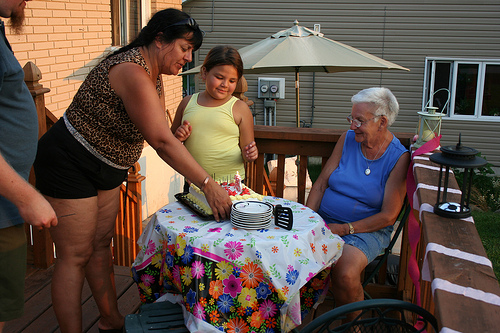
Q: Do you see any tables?
A: Yes, there is a table.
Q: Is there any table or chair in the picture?
A: Yes, there is a table.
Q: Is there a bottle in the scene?
A: No, there are no bottles.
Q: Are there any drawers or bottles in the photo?
A: No, there are no bottles or drawers.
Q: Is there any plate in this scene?
A: Yes, there is a plate.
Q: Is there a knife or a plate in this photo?
A: Yes, there is a plate.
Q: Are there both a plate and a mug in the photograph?
A: No, there is a plate but no mugs.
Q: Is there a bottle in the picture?
A: No, there are no bottles.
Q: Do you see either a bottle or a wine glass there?
A: No, there are no bottles or wine glasses.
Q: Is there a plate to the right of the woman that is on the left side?
A: Yes, there is a plate to the right of the woman.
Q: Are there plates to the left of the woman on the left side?
A: No, the plate is to the right of the woman.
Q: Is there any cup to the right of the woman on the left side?
A: No, there is a plate to the right of the woman.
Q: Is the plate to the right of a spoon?
A: No, the plate is to the right of the woman.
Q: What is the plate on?
A: The plate is on the table.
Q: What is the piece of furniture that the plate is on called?
A: The piece of furniture is a table.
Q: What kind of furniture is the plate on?
A: The plate is on the table.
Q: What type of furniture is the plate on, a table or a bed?
A: The plate is on a table.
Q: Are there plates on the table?
A: Yes, there is a plate on the table.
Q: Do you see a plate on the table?
A: Yes, there is a plate on the table.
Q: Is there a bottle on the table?
A: No, there is a plate on the table.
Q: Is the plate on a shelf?
A: No, the plate is on the table.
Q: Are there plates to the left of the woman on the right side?
A: Yes, there is a plate to the left of the woman.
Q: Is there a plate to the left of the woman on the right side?
A: Yes, there is a plate to the left of the woman.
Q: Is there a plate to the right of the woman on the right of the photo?
A: No, the plate is to the left of the woman.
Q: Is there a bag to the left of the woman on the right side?
A: No, there is a plate to the left of the woman.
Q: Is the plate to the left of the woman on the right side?
A: Yes, the plate is to the left of the woman.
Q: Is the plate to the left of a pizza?
A: No, the plate is to the left of the woman.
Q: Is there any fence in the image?
A: No, there are no fences.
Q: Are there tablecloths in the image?
A: Yes, there is a tablecloth.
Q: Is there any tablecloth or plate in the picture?
A: Yes, there is a tablecloth.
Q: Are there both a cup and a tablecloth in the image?
A: No, there is a tablecloth but no cups.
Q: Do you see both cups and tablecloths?
A: No, there is a tablecloth but no cups.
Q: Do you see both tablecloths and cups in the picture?
A: No, there is a tablecloth but no cups.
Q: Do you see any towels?
A: No, there are no towels.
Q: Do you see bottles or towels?
A: No, there are no towels or bottles.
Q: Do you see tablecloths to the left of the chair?
A: Yes, there is a tablecloth to the left of the chair.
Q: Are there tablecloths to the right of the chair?
A: No, the tablecloth is to the left of the chair.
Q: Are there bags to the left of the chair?
A: No, there is a tablecloth to the left of the chair.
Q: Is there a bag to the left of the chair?
A: No, there is a tablecloth to the left of the chair.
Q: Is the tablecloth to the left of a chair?
A: Yes, the tablecloth is to the left of a chair.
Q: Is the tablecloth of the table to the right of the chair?
A: No, the tablecloth is to the left of the chair.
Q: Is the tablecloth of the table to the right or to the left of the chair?
A: The tablecloth is to the left of the chair.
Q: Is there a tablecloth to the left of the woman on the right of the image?
A: Yes, there is a tablecloth to the left of the woman.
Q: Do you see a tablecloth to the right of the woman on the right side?
A: No, the tablecloth is to the left of the woman.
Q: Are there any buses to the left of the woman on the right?
A: No, there is a tablecloth to the left of the woman.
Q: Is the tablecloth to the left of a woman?
A: Yes, the tablecloth is to the left of a woman.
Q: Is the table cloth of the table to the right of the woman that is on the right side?
A: No, the tablecloth is to the left of the woman.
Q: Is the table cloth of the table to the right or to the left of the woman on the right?
A: The tablecloth is to the left of the woman.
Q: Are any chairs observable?
A: Yes, there is a chair.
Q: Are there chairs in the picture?
A: Yes, there is a chair.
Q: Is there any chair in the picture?
A: Yes, there is a chair.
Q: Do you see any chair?
A: Yes, there is a chair.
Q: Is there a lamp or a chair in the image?
A: Yes, there is a chair.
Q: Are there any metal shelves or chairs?
A: Yes, there is a metal chair.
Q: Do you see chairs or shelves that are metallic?
A: Yes, the chair is metallic.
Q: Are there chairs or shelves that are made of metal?
A: Yes, the chair is made of metal.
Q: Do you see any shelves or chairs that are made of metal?
A: Yes, the chair is made of metal.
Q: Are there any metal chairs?
A: Yes, there is a metal chair.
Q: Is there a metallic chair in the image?
A: Yes, there is a metal chair.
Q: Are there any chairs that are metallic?
A: Yes, there is a chair that is metallic.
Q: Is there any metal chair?
A: Yes, there is a chair that is made of metal.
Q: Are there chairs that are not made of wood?
A: Yes, there is a chair that is made of metal.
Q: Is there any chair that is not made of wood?
A: Yes, there is a chair that is made of metal.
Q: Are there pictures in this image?
A: No, there are no pictures.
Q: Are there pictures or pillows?
A: No, there are no pictures or pillows.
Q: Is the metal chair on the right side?
A: Yes, the chair is on the right of the image.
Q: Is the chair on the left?
A: No, the chair is on the right of the image.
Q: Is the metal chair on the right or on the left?
A: The chair is on the right of the image.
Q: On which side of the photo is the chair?
A: The chair is on the right of the image.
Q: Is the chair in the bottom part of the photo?
A: Yes, the chair is in the bottom of the image.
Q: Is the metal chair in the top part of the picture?
A: No, the chair is in the bottom of the image.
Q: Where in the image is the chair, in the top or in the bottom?
A: The chair is in the bottom of the image.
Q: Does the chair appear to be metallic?
A: Yes, the chair is metallic.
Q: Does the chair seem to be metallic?
A: Yes, the chair is metallic.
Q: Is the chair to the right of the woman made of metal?
A: Yes, the chair is made of metal.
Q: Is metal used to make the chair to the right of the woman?
A: Yes, the chair is made of metal.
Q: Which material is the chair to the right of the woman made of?
A: The chair is made of metal.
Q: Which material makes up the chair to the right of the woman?
A: The chair is made of metal.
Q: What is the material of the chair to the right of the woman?
A: The chair is made of metal.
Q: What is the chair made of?
A: The chair is made of metal.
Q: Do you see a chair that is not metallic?
A: No, there is a chair but it is metallic.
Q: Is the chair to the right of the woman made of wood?
A: No, the chair is made of metal.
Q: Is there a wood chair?
A: No, there is a chair but it is made of metal.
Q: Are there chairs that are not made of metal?
A: No, there is a chair but it is made of metal.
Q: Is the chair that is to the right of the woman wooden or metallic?
A: The chair is metallic.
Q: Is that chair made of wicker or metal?
A: The chair is made of metal.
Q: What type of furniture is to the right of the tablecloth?
A: The piece of furniture is a chair.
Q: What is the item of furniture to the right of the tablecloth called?
A: The piece of furniture is a chair.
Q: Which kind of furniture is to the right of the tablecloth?
A: The piece of furniture is a chair.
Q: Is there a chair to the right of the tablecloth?
A: Yes, there is a chair to the right of the tablecloth.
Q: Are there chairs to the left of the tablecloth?
A: No, the chair is to the right of the tablecloth.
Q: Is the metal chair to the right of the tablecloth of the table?
A: Yes, the chair is to the right of the tablecloth.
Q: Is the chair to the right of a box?
A: No, the chair is to the right of the tablecloth.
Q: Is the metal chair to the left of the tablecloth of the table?
A: No, the chair is to the right of the tablecloth.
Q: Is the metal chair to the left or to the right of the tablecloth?
A: The chair is to the right of the tablecloth.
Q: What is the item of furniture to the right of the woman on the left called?
A: The piece of furniture is a chair.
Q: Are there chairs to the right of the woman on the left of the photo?
A: Yes, there is a chair to the right of the woman.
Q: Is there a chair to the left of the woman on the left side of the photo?
A: No, the chair is to the right of the woman.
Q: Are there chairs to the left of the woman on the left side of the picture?
A: No, the chair is to the right of the woman.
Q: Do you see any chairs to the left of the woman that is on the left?
A: No, the chair is to the right of the woman.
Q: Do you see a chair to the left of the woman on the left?
A: No, the chair is to the right of the woman.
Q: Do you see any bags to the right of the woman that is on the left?
A: No, there is a chair to the right of the woman.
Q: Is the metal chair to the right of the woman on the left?
A: Yes, the chair is to the right of the woman.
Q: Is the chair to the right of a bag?
A: No, the chair is to the right of the woman.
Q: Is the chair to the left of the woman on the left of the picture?
A: No, the chair is to the right of the woman.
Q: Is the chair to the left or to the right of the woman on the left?
A: The chair is to the right of the woman.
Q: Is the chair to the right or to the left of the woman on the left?
A: The chair is to the right of the woman.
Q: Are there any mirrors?
A: No, there are no mirrors.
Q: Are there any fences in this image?
A: No, there are no fences.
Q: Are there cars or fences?
A: No, there are no fences or cars.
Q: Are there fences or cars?
A: No, there are no fences or cars.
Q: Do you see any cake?
A: Yes, there is a cake.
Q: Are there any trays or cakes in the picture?
A: Yes, there is a cake.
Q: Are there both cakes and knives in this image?
A: No, there is a cake but no knives.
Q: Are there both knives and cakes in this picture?
A: No, there is a cake but no knives.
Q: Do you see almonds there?
A: No, there are no almonds.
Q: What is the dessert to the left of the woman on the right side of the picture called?
A: The dessert is a cake.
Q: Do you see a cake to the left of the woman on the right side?
A: Yes, there is a cake to the left of the woman.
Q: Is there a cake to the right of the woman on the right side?
A: No, the cake is to the left of the woman.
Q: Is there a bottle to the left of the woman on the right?
A: No, there is a cake to the left of the woman.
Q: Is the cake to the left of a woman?
A: Yes, the cake is to the left of a woman.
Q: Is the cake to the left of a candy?
A: No, the cake is to the left of a woman.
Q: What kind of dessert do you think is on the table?
A: The dessert is a cake.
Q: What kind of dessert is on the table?
A: The dessert is a cake.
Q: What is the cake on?
A: The cake is on the table.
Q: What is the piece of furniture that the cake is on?
A: The piece of furniture is a table.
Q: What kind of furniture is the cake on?
A: The cake is on the table.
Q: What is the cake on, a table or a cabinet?
A: The cake is on a table.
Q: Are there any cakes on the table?
A: Yes, there is a cake on the table.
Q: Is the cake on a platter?
A: No, the cake is on the table.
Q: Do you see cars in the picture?
A: No, there are no cars.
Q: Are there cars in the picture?
A: No, there are no cars.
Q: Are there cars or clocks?
A: No, there are no cars or clocks.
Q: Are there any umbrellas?
A: Yes, there is an umbrella.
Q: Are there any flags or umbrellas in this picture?
A: Yes, there is an umbrella.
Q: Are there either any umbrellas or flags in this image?
A: Yes, there is an umbrella.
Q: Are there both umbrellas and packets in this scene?
A: No, there is an umbrella but no packets.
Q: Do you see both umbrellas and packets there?
A: No, there is an umbrella but no packets.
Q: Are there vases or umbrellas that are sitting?
A: Yes, the umbrella is sitting.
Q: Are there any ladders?
A: No, there are no ladders.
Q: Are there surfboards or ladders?
A: No, there are no ladders or surfboards.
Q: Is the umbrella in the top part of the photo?
A: Yes, the umbrella is in the top of the image.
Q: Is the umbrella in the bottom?
A: No, the umbrella is in the top of the image.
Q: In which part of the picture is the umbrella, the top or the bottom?
A: The umbrella is in the top of the image.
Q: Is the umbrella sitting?
A: Yes, the umbrella is sitting.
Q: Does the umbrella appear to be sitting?
A: Yes, the umbrella is sitting.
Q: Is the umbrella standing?
A: No, the umbrella is sitting.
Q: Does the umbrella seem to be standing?
A: No, the umbrella is sitting.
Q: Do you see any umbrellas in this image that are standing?
A: No, there is an umbrella but it is sitting.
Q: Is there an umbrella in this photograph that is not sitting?
A: No, there is an umbrella but it is sitting.